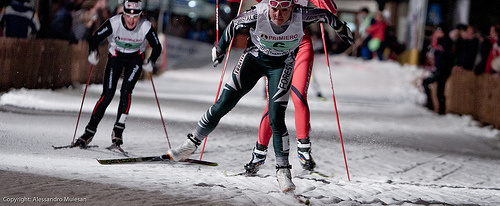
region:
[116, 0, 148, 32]
Head of athletic skier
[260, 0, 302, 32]
Head of athletic skier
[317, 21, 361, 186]
Red ski pole of skier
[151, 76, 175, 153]
Ski pole of athlete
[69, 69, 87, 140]
Ski pole of athlete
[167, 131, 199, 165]
Foot of athletic skier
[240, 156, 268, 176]
Foot of athletic skier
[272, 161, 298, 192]
Foot of athletic skier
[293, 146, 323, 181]
Foot of athletic skier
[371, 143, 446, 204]
Ski tracks in snow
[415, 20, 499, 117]
people standing around while watching the skiiers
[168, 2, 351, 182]
the person in the lead of the race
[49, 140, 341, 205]
the skiis the people are wearing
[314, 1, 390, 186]
a red pole with the flag on top of it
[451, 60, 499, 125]
a wooden fence in front of the people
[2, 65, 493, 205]
the snow on the ground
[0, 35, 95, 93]
another wooden fence in front of the people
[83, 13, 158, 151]
a person in a black outfit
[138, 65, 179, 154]
the ski pole the man is holding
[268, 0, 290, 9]
the goggles on the persons face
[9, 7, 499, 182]
this is a ski race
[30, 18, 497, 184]
these men are going fast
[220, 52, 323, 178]
the man's pants are green and white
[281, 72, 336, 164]
the man's pants are red and black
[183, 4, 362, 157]
the man is holding ski poles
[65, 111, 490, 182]
these men are skiing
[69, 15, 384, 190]
there are three men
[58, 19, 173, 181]
the man's uniform is black and white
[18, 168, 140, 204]
the ground is covered in smooth snow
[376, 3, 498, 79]
these people are spectators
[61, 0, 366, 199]
three people skiing on snow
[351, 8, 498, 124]
crowd watching three skiers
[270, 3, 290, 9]
white goggles on skiers head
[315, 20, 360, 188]
pink and white ski pole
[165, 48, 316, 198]
black pants on skier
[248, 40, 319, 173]
pink pants on skier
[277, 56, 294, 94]
logo on skiers pants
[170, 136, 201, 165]
white ski boot on foot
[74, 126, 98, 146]
black ski boot on foot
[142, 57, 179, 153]
red ski pole in snow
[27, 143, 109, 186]
White snow on the ground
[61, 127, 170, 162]
Skis under a person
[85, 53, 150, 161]
Black ski pants on a person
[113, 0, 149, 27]
Goggles on a person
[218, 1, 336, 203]
Person cross country skiing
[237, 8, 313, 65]
Vest on a skier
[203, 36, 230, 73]
Gloves on a skier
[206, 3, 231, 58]
Ski pole in a hand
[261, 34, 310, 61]
Number on a person sking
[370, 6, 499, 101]
People watching a ski race